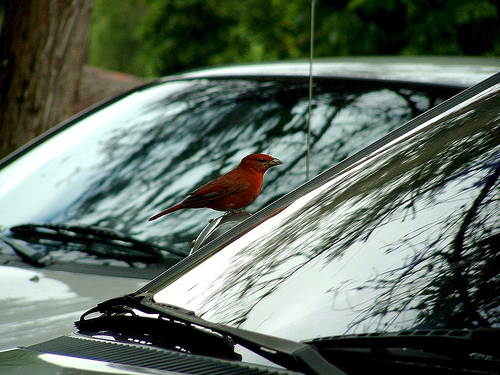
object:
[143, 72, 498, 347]
screen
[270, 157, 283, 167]
beak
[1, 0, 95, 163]
tree trunk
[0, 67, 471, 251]
window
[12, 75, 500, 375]
windscreens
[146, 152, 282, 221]
bird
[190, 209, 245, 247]
side mirror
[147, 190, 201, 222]
feathers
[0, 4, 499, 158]
trees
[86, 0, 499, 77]
leaves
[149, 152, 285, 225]
bird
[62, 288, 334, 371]
wiper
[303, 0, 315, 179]
antennae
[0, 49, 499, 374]
car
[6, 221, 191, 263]
wiper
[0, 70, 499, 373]
car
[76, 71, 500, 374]
window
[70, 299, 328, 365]
slits